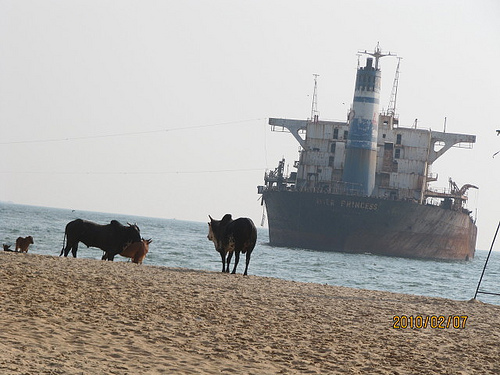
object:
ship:
[254, 38, 482, 265]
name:
[314, 198, 378, 211]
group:
[58, 212, 259, 278]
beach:
[0, 250, 500, 375]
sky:
[2, 0, 499, 251]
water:
[0, 201, 190, 265]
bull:
[206, 213, 257, 278]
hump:
[221, 213, 233, 223]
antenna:
[357, 40, 398, 70]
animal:
[58, 217, 154, 265]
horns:
[146, 237, 153, 241]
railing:
[433, 132, 475, 150]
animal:
[14, 235, 34, 254]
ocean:
[0, 199, 500, 305]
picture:
[2, 0, 500, 375]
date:
[391, 313, 470, 330]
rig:
[386, 56, 404, 116]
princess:
[340, 200, 378, 212]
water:
[194, 220, 500, 307]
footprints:
[110, 350, 130, 363]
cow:
[2, 243, 13, 252]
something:
[467, 222, 499, 301]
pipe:
[342, 66, 381, 196]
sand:
[137, 315, 319, 352]